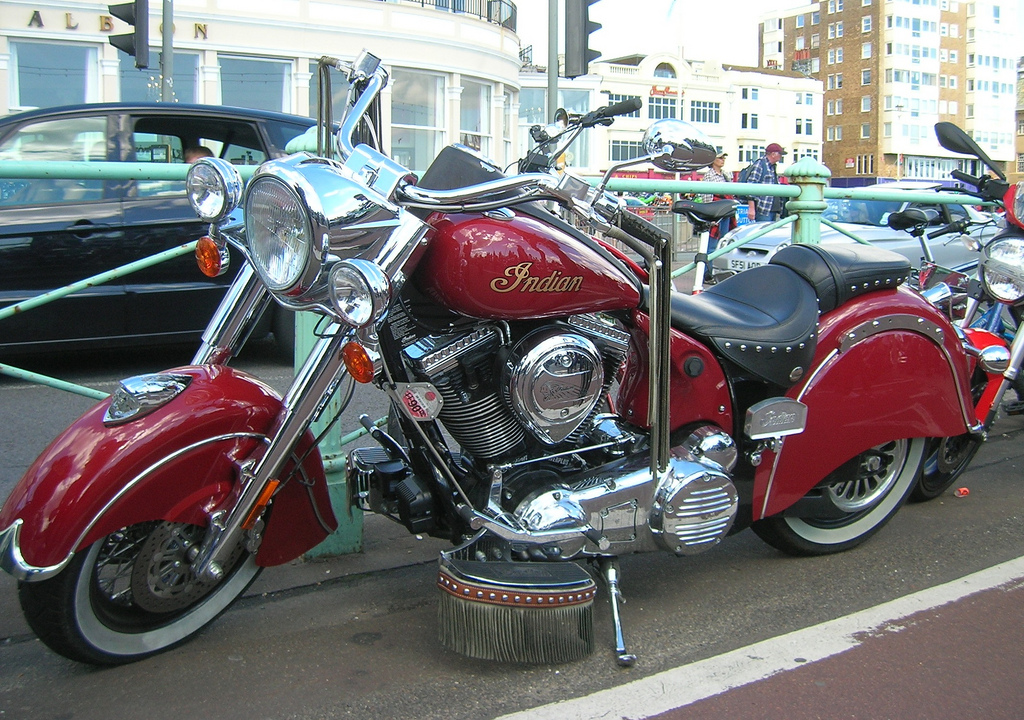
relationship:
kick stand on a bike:
[597, 554, 641, 667] [2, 68, 1007, 670]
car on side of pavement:
[1, 97, 349, 366] [0, 214, 1024, 719]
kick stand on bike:
[592, 557, 638, 667] [2, 68, 1007, 670]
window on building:
[120, 43, 200, 117] [1, 0, 526, 189]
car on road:
[0, 102, 339, 366] [270, 589, 977, 715]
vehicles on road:
[711, 176, 992, 280] [270, 589, 977, 715]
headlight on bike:
[238, 167, 323, 297] [2, 52, 1003, 688]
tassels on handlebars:
[639, 239, 676, 469] [635, 224, 679, 473]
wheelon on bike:
[2, 362, 352, 678] [2, 68, 1007, 670]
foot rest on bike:
[433, 558, 596, 666] [2, 68, 1007, 670]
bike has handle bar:
[2, 68, 1007, 670] [337, 45, 593, 231]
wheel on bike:
[773, 421, 936, 577] [2, 68, 1007, 670]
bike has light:
[2, 52, 1003, 688] [229, 153, 333, 316]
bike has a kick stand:
[2, 68, 1007, 670] [583, 547, 644, 664]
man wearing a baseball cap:
[731, 143, 787, 223] [758, 137, 787, 150]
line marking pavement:
[680, 642, 776, 705] [676, 586, 774, 625]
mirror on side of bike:
[933, 111, 990, 179] [153, 124, 975, 663]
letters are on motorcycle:
[496, 264, 592, 303] [99, 102, 977, 614]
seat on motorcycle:
[691, 269, 795, 352] [99, 102, 977, 614]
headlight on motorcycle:
[231, 169, 324, 297] [93, 91, 986, 668]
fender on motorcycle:
[34, 402, 277, 519] [15, 195, 990, 634]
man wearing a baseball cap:
[751, 217, 965, 459] [765, 143, 788, 155]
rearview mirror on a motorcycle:
[635, 109, 728, 172] [183, 106, 972, 655]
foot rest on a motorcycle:
[434, 551, 609, 668] [207, 113, 992, 611]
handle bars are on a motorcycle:
[332, 65, 598, 217] [34, 106, 992, 686]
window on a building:
[646, 93, 677, 115] [633, 72, 815, 137]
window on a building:
[391, 67, 446, 129] [393, 14, 512, 140]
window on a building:
[397, 80, 449, 126] [378, 13, 523, 148]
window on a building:
[693, 104, 733, 124] [620, 50, 811, 143]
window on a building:
[734, 109, 761, 133] [633, 59, 808, 133]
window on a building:
[792, 119, 823, 135] [631, 52, 824, 146]